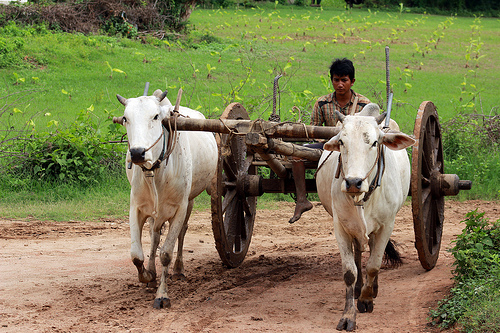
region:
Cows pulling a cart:
[122, 83, 412, 329]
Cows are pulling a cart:
[102, 85, 419, 332]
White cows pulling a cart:
[115, 81, 426, 331]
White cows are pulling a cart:
[109, 75, 413, 328]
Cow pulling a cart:
[103, 90, 233, 313]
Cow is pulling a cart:
[102, 82, 227, 314]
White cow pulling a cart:
[110, 78, 227, 313]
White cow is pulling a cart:
[103, 84, 224, 311]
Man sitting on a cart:
[285, 56, 397, 224]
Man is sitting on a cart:
[287, 50, 394, 225]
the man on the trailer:
[286, 56, 366, 223]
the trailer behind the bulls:
[210, 100, 470, 270]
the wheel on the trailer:
[210, 102, 255, 265]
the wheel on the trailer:
[410, 100, 445, 270]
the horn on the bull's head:
[333, 108, 344, 120]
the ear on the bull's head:
[378, 130, 415, 150]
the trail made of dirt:
[0, 198, 498, 330]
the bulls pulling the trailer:
[115, 88, 414, 330]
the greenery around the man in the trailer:
[0, 1, 498, 331]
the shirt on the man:
[309, 89, 369, 126]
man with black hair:
[322, 43, 362, 120]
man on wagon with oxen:
[102, 49, 471, 325]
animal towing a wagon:
[100, 78, 217, 310]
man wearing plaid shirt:
[293, 33, 400, 135]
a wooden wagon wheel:
[204, 83, 263, 283]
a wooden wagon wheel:
[407, 90, 458, 280]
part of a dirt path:
[191, 273, 290, 328]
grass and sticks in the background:
[18, 80, 93, 190]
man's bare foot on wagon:
[277, 156, 314, 226]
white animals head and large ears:
[309, 101, 407, 205]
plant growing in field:
[455, 101, 475, 111]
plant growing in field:
[453, 77, 480, 92]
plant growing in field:
[461, 61, 481, 76]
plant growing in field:
[458, 48, 487, 63]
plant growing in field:
[463, 32, 483, 51]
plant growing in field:
[465, 22, 478, 32]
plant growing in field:
[393, 78, 412, 98]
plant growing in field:
[399, 63, 415, 83]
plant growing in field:
[408, 40, 422, 61]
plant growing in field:
[424, 35, 438, 49]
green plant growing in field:
[457, 73, 477, 93]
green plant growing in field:
[461, 52, 488, 72]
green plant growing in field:
[463, 40, 488, 55]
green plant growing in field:
[12, 98, 37, 121]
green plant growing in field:
[16, 69, 43, 88]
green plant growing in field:
[58, 85, 79, 104]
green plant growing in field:
[100, 57, 130, 82]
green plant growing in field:
[160, 73, 182, 96]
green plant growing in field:
[190, 55, 202, 82]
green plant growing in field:
[204, 60, 219, 80]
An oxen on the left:
[112, 77, 212, 296]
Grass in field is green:
[63, 75, 105, 107]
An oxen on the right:
[325, 110, 400, 325]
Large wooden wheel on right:
[402, 97, 457, 272]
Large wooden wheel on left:
[196, 95, 257, 267]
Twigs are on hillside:
[25, 2, 175, 35]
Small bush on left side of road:
[5, 128, 121, 191]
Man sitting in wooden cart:
[302, 52, 367, 123]